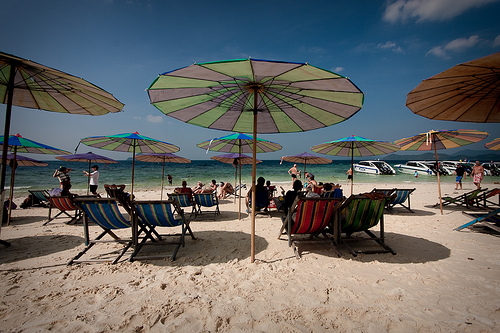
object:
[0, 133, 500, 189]
water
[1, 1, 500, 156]
sky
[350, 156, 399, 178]
boat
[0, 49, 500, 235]
umbrellas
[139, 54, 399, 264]
big umbrella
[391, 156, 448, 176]
boat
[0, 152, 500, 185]
ocean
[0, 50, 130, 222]
umbrella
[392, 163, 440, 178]
boat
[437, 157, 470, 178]
boat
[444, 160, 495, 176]
boat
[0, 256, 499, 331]
beach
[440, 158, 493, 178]
boat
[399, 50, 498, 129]
umbrella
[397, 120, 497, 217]
umbrella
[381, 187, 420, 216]
chair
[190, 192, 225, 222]
chair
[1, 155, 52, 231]
umbrella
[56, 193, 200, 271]
chairs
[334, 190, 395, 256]
chair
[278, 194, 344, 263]
chair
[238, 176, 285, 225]
man beach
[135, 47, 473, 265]
umbrella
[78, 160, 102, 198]
woman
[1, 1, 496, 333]
picture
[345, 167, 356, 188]
standing man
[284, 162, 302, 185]
standing man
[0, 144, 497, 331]
beach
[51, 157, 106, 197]
two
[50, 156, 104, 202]
people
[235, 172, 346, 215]
people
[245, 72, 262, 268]
pole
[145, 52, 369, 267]
umbrella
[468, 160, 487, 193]
man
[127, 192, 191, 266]
chair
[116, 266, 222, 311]
foot prints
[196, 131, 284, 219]
umbrella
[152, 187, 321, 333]
sand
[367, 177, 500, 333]
sand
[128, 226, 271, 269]
shadow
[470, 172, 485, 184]
shorts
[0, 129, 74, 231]
umbrella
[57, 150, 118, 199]
umbrella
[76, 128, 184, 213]
umbrella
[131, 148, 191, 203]
umbrella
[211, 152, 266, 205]
umbrella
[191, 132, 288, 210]
umbrella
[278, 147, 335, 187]
umbrella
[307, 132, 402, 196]
umbrella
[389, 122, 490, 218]
umbrella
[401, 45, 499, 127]
umbrella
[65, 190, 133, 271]
beach chair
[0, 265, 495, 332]
sand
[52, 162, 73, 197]
person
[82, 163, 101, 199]
person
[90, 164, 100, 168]
cap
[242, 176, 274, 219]
man